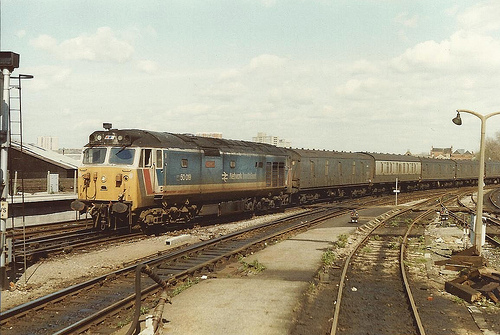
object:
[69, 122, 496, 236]
train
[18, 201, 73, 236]
track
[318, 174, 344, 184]
dirt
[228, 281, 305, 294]
pavement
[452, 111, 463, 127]
light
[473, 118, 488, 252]
pole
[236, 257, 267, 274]
grass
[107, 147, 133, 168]
window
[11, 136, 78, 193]
building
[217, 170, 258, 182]
name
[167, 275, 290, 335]
ground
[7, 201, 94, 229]
platform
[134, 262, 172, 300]
wood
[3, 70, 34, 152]
ladder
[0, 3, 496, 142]
sky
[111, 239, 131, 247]
scraps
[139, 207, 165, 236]
wheel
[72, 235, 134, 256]
mud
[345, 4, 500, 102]
clouds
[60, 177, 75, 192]
fence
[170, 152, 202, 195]
door